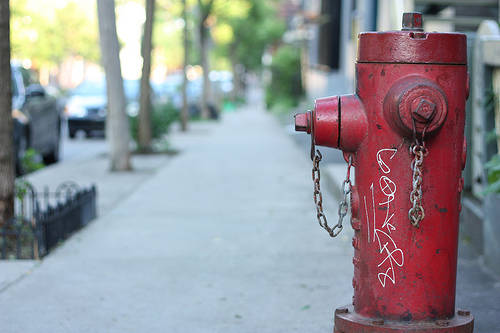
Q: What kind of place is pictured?
A: It is a sidewalk.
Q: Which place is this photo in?
A: It is at the sidewalk.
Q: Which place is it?
A: It is a sidewalk.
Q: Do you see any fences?
A: Yes, there is a fence.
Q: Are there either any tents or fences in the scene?
A: Yes, there is a fence.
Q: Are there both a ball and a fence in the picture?
A: No, there is a fence but no balls.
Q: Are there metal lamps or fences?
A: Yes, there is a metal fence.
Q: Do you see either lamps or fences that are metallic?
A: Yes, the fence is metallic.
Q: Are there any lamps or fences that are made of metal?
A: Yes, the fence is made of metal.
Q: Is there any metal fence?
A: Yes, there is a fence that is made of metal.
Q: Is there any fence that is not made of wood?
A: Yes, there is a fence that is made of metal.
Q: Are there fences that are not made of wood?
A: Yes, there is a fence that is made of metal.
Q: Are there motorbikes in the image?
A: No, there are no motorbikes.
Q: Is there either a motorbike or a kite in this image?
A: No, there are no motorcycles or kites.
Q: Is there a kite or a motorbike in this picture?
A: No, there are no motorcycles or kites.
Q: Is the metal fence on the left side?
A: Yes, the fence is on the left of the image.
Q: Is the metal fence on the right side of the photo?
A: No, the fence is on the left of the image.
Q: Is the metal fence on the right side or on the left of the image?
A: The fence is on the left of the image.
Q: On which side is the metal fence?
A: The fence is on the left of the image.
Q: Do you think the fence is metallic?
A: Yes, the fence is metallic.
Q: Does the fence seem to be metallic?
A: Yes, the fence is metallic.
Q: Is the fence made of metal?
A: Yes, the fence is made of metal.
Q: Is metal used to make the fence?
A: Yes, the fence is made of metal.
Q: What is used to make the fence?
A: The fence is made of metal.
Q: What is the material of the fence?
A: The fence is made of metal.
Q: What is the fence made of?
A: The fence is made of metal.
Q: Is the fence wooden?
A: No, the fence is metallic.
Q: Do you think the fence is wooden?
A: No, the fence is metallic.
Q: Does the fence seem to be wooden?
A: No, the fence is metallic.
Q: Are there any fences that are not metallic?
A: No, there is a fence but it is metallic.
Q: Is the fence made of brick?
A: No, the fence is made of metal.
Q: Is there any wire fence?
A: No, there is a fence but it is made of metal.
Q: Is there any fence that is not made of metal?
A: No, there is a fence but it is made of metal.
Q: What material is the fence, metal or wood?
A: The fence is made of metal.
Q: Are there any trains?
A: No, there are no trains.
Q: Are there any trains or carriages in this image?
A: No, there are no trains or carriages.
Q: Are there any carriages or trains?
A: No, there are no trains or carriages.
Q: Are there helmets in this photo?
A: No, there are no helmets.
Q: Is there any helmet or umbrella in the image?
A: No, there are no helmets or umbrellas.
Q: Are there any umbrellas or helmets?
A: No, there are no helmets or umbrellas.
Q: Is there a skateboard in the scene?
A: No, there are no skateboards.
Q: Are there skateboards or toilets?
A: No, there are no skateboards or toilets.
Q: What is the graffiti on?
A: The graffiti is on the fire hydrant.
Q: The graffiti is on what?
A: The graffiti is on the fire hydrant.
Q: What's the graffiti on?
A: The graffiti is on the fire hydrant.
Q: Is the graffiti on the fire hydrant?
A: Yes, the graffiti is on the fire hydrant.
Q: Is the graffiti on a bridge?
A: No, the graffiti is on the fire hydrant.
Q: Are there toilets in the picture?
A: No, there are no toilets.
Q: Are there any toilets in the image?
A: No, there are no toilets.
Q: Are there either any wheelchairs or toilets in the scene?
A: No, there are no toilets or wheelchairs.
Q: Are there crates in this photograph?
A: No, there are no crates.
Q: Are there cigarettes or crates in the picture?
A: No, there are no crates or cigarettes.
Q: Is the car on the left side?
A: Yes, the car is on the left of the image.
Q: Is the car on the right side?
A: No, the car is on the left of the image.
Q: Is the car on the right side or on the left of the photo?
A: The car is on the left of the image.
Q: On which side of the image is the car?
A: The car is on the left of the image.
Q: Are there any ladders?
A: No, there are no ladders.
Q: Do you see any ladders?
A: No, there are no ladders.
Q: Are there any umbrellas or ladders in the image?
A: No, there are no ladders or umbrellas.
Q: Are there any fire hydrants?
A: Yes, there is a fire hydrant.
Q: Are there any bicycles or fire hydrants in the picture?
A: Yes, there is a fire hydrant.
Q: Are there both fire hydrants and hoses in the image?
A: No, there is a fire hydrant but no hoses.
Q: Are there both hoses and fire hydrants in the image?
A: No, there is a fire hydrant but no hoses.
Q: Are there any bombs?
A: No, there are no bombs.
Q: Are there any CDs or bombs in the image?
A: No, there are no bombs or cds.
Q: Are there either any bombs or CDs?
A: No, there are no bombs or cds.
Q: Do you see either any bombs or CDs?
A: No, there are no bombs or cds.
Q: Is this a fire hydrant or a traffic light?
A: This is a fire hydrant.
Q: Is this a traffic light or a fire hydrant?
A: This is a fire hydrant.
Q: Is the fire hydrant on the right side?
A: Yes, the fire hydrant is on the right of the image.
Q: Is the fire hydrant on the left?
A: No, the fire hydrant is on the right of the image.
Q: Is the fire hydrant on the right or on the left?
A: The fire hydrant is on the right of the image.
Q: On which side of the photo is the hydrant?
A: The hydrant is on the right of the image.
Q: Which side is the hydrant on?
A: The hydrant is on the right of the image.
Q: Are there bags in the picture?
A: No, there are no bags.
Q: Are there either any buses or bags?
A: No, there are no bags or buses.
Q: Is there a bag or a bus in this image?
A: No, there are no bags or buses.